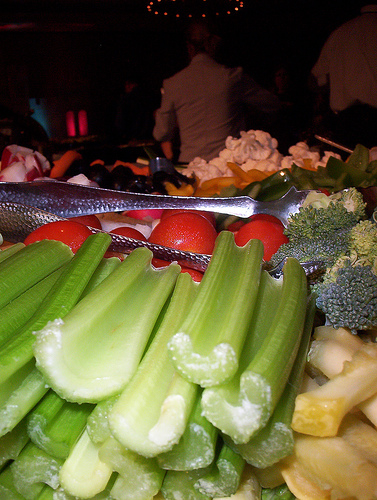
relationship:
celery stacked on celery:
[167, 230, 262, 388] [42, 244, 185, 408]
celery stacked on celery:
[0, 230, 319, 498] [159, 395, 223, 473]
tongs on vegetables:
[7, 176, 350, 283] [26, 223, 371, 314]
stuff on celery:
[223, 398, 272, 444] [199, 251, 313, 450]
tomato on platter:
[0, 209, 291, 280] [10, 134, 368, 490]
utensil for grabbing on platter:
[7, 164, 337, 281] [10, 134, 368, 490]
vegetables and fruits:
[7, 162, 373, 495] [9, 137, 364, 217]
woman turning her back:
[152, 21, 255, 166] [178, 64, 230, 162]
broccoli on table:
[271, 190, 373, 331] [0, 151, 365, 498]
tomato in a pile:
[0, 209, 291, 280] [21, 210, 288, 268]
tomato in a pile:
[151, 209, 218, 256] [21, 210, 288, 268]